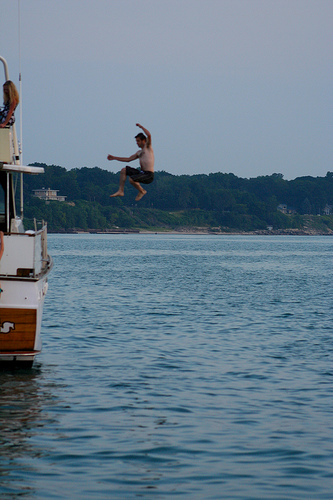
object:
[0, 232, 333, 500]
water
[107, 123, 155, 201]
person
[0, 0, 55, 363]
boat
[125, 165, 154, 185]
pants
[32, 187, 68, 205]
home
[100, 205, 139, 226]
hill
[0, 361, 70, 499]
reflection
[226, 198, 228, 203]
trees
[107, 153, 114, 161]
hands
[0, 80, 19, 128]
woman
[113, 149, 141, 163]
arms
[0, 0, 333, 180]
sky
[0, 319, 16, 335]
s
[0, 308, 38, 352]
wood grain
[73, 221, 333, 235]
beach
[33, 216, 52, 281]
rail